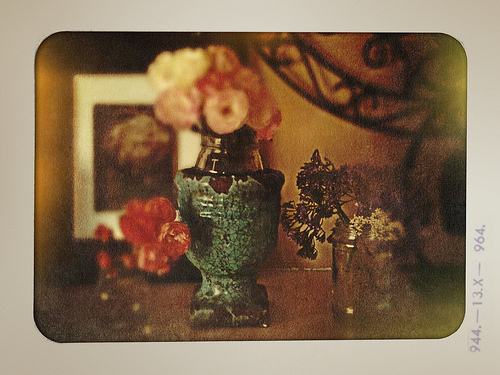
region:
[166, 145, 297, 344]
this is a vase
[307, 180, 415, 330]
this is a vase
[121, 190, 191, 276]
this is a flower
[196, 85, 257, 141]
this is a flower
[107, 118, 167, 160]
this is a flower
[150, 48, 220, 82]
this is a flower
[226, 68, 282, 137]
this is a flower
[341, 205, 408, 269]
this is a flower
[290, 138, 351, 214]
this is a flower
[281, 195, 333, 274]
this is a flower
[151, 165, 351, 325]
the vase is unique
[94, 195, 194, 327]
the flowers are red & lovely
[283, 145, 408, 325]
the purple flowers are pretty as well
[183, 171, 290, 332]
the vase is green & brown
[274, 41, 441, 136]
this appears to be wrought iron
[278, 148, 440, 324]
flowers in a glass jar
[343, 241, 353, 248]
light glare on the jar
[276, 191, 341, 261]
flower is leaning over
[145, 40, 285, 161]
bouquet of pastel flowers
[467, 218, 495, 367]
writing that is sideways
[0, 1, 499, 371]
thick gray border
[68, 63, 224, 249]
thick white frame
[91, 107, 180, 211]
blurry picture in the frame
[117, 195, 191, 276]
bouquet of red flowers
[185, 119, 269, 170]
top of the vase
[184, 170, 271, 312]
the vase is green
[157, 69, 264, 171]
roses in the vase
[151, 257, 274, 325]
bottom of the vase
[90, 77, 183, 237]
picture on the wall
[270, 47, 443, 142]
fixture on the wall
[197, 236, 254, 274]
cracked pattern on vase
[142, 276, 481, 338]
tan border around picture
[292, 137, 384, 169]
tan on the wall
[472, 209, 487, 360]
writing on side of picture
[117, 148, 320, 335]
a ceramic vase on table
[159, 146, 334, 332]
an old vase on the table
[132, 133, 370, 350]
a ceramic vase on table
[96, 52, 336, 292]
flowers on display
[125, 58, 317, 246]
flowers on display on a table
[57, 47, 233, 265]
a picture on the table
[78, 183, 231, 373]
a single flower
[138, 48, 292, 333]
A green and glass vase.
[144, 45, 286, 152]
Pink flowers in the vase.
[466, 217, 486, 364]
Information on the boarder of the photo.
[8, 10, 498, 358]
A grey boarder around the picture.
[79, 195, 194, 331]
Pink flowers in a low glass vase.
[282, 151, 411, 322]
Purple and white flowers in a glass jar.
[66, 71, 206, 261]
A white framed picture on the table.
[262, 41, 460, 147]
A metal wired object in the background.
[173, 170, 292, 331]
A green pattern on the vase.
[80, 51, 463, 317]
Flowers on a table.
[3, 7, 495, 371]
Decorative items, arranged on blurry surface.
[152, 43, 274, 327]
Fake flowers in glass, inside painted cup.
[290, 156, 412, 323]
Dried, brown and white blooms in glass.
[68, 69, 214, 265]
Framed art, standing, beyond floral objects.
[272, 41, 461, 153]
Black, metal, decorative object, on yellow wall.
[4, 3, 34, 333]
Grey border of photo.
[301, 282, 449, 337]
Blurry and shiny surface, showing brown and green.